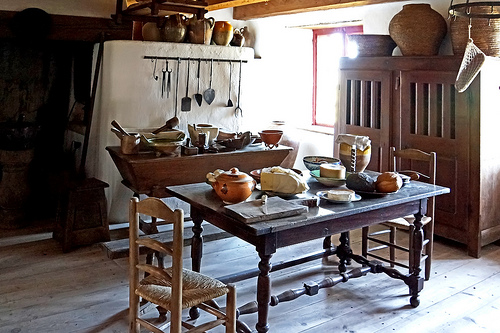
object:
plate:
[316, 189, 362, 203]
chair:
[127, 197, 237, 333]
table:
[284, 203, 371, 232]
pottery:
[206, 167, 257, 205]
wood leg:
[404, 213, 425, 307]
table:
[166, 180, 212, 202]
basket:
[387, 3, 447, 57]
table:
[291, 224, 329, 243]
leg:
[335, 230, 353, 283]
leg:
[255, 248, 277, 333]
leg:
[191, 218, 205, 273]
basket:
[446, 1, 500, 57]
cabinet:
[332, 55, 500, 260]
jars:
[182, 16, 215, 46]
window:
[312, 25, 363, 128]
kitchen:
[0, 0, 500, 333]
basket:
[347, 34, 397, 59]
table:
[398, 187, 432, 213]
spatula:
[181, 57, 192, 111]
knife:
[259, 194, 268, 214]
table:
[340, 191, 384, 219]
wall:
[0, 0, 200, 238]